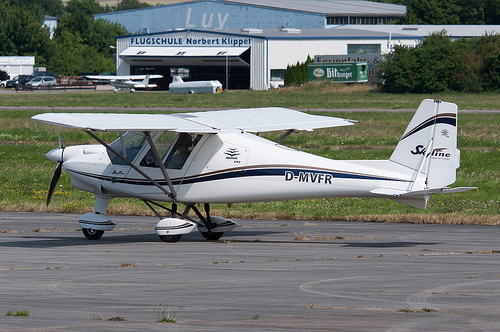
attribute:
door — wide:
[119, 46, 249, 86]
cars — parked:
[7, 72, 59, 89]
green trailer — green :
[307, 62, 367, 85]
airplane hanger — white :
[112, 22, 428, 91]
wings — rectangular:
[25, 70, 362, 165]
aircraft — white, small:
[31, 57, 498, 280]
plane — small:
[30, 97, 481, 232]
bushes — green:
[372, 26, 497, 97]